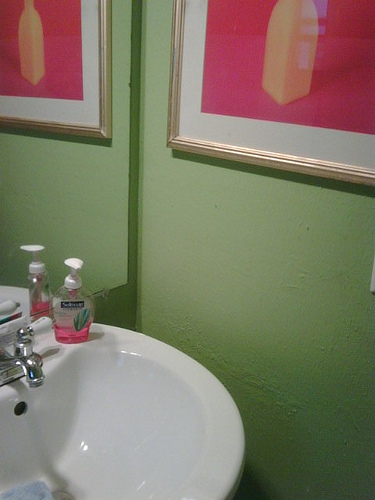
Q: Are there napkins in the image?
A: No, there are no napkins.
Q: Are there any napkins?
A: No, there are no napkins.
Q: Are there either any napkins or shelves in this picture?
A: No, there are no napkins or shelves.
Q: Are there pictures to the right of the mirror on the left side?
A: Yes, there is a picture to the right of the mirror.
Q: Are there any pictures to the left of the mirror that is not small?
A: No, the picture is to the right of the mirror.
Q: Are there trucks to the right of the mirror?
A: No, there is a picture to the right of the mirror.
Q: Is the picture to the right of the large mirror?
A: Yes, the picture is to the right of the mirror.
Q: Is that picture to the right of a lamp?
A: No, the picture is to the right of the mirror.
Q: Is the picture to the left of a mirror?
A: No, the picture is to the right of a mirror.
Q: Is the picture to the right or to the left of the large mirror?
A: The picture is to the right of the mirror.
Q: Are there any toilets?
A: No, there are no toilets.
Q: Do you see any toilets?
A: No, there are no toilets.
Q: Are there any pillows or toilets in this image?
A: No, there are no toilets or pillows.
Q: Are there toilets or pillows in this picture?
A: No, there are no toilets or pillows.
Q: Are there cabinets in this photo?
A: No, there are no cabinets.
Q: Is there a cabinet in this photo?
A: No, there are no cabinets.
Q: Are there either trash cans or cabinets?
A: No, there are no cabinets or trash cans.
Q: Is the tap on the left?
A: Yes, the tap is on the left of the image.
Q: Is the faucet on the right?
A: No, the faucet is on the left of the image.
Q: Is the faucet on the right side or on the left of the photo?
A: The faucet is on the left of the image.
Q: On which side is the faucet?
A: The faucet is on the left of the image.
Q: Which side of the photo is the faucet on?
A: The faucet is on the left of the image.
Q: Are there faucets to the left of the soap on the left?
A: Yes, there is a faucet to the left of the soap.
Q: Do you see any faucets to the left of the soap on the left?
A: Yes, there is a faucet to the left of the soap.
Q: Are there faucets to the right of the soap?
A: No, the faucet is to the left of the soap.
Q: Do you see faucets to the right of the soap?
A: No, the faucet is to the left of the soap.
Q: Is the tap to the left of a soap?
A: Yes, the tap is to the left of a soap.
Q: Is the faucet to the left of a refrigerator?
A: No, the faucet is to the left of a soap.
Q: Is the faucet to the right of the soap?
A: No, the faucet is to the left of the soap.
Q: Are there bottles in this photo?
A: Yes, there is a bottle.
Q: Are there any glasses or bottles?
A: Yes, there is a bottle.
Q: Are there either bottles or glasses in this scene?
A: Yes, there is a bottle.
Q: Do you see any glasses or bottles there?
A: Yes, there is a bottle.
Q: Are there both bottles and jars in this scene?
A: No, there is a bottle but no jars.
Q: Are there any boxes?
A: No, there are no boxes.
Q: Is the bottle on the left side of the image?
A: Yes, the bottle is on the left of the image.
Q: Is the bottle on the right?
A: No, the bottle is on the left of the image.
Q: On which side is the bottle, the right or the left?
A: The bottle is on the left of the image.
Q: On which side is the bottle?
A: The bottle is on the left of the image.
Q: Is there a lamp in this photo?
A: No, there are no lamps.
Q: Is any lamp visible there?
A: No, there are no lamps.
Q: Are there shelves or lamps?
A: No, there are no lamps or shelves.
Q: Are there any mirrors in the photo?
A: Yes, there is a mirror.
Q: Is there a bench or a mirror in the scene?
A: Yes, there is a mirror.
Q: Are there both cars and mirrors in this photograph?
A: No, there is a mirror but no cars.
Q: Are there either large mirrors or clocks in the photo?
A: Yes, there is a large mirror.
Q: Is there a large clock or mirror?
A: Yes, there is a large mirror.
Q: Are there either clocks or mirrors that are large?
A: Yes, the mirror is large.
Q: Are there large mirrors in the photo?
A: Yes, there is a large mirror.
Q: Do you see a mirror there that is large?
A: Yes, there is a mirror that is large.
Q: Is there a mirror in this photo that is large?
A: Yes, there is a mirror that is large.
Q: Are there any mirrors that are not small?
A: Yes, there is a large mirror.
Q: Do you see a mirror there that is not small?
A: Yes, there is a large mirror.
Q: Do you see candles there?
A: No, there are no candles.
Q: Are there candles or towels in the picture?
A: No, there are no candles or towels.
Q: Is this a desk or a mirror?
A: This is a mirror.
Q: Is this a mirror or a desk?
A: This is a mirror.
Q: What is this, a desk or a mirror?
A: This is a mirror.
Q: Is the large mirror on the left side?
A: Yes, the mirror is on the left of the image.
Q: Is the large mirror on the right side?
A: No, the mirror is on the left of the image.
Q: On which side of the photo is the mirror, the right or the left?
A: The mirror is on the left of the image.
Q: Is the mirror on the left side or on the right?
A: The mirror is on the left of the image.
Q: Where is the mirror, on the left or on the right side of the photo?
A: The mirror is on the left of the image.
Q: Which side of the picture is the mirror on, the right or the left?
A: The mirror is on the left of the image.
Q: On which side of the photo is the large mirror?
A: The mirror is on the left of the image.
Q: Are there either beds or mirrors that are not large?
A: No, there is a mirror but it is large.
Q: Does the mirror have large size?
A: Yes, the mirror is large.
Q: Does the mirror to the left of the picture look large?
A: Yes, the mirror is large.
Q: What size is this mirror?
A: The mirror is large.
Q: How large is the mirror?
A: The mirror is large.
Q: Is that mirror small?
A: No, the mirror is large.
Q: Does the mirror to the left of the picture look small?
A: No, the mirror is large.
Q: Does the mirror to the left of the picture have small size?
A: No, the mirror is large.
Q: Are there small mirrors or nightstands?
A: No, there is a mirror but it is large.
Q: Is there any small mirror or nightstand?
A: No, there is a mirror but it is large.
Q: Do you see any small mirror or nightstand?
A: No, there is a mirror but it is large.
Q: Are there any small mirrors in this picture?
A: No, there is a mirror but it is large.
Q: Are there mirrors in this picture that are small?
A: No, there is a mirror but it is large.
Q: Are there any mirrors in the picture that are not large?
A: No, there is a mirror but it is large.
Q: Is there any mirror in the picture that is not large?
A: No, there is a mirror but it is large.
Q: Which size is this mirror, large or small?
A: The mirror is large.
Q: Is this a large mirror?
A: Yes, this is a large mirror.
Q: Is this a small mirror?
A: No, this is a large mirror.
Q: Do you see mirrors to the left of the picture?
A: Yes, there is a mirror to the left of the picture.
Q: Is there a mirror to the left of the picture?
A: Yes, there is a mirror to the left of the picture.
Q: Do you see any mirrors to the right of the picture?
A: No, the mirror is to the left of the picture.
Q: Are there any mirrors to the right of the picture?
A: No, the mirror is to the left of the picture.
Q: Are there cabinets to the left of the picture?
A: No, there is a mirror to the left of the picture.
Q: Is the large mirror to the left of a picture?
A: Yes, the mirror is to the left of a picture.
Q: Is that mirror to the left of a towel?
A: No, the mirror is to the left of a picture.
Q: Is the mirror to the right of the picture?
A: No, the mirror is to the left of the picture.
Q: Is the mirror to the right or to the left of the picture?
A: The mirror is to the left of the picture.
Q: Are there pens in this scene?
A: No, there are no pens.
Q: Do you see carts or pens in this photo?
A: No, there are no pens or carts.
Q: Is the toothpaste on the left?
A: Yes, the toothpaste is on the left of the image.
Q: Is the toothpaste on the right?
A: No, the toothpaste is on the left of the image.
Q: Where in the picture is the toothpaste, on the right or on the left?
A: The toothpaste is on the left of the image.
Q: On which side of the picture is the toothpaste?
A: The toothpaste is on the left of the image.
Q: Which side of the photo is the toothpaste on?
A: The toothpaste is on the left of the image.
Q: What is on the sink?
A: The toothpaste is on the sink.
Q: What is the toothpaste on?
A: The toothpaste is on the sink.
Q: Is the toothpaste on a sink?
A: Yes, the toothpaste is on a sink.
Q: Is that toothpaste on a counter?
A: No, the toothpaste is on a sink.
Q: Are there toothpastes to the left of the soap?
A: Yes, there is a toothpaste to the left of the soap.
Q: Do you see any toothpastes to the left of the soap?
A: Yes, there is a toothpaste to the left of the soap.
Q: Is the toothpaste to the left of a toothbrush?
A: No, the toothpaste is to the left of the soap.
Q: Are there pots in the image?
A: No, there are no pots.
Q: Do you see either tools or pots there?
A: No, there are no pots or tools.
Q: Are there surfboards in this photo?
A: No, there are no surfboards.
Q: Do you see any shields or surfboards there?
A: No, there are no surfboards or shields.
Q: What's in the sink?
A: The drain is in the sink.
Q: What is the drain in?
A: The drain is in the sink.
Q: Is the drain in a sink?
A: Yes, the drain is in a sink.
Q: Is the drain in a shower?
A: No, the drain is in a sink.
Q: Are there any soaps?
A: Yes, there is a soap.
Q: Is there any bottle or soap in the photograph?
A: Yes, there is a soap.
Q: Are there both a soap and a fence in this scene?
A: No, there is a soap but no fences.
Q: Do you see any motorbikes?
A: No, there are no motorbikes.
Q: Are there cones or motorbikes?
A: No, there are no motorbikes or cones.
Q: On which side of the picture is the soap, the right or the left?
A: The soap is on the left of the image.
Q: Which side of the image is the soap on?
A: The soap is on the left of the image.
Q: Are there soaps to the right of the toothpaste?
A: Yes, there is a soap to the right of the toothpaste.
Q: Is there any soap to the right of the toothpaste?
A: Yes, there is a soap to the right of the toothpaste.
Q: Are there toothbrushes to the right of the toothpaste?
A: No, there is a soap to the right of the toothpaste.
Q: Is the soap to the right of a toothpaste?
A: Yes, the soap is to the right of a toothpaste.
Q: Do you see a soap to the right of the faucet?
A: Yes, there is a soap to the right of the faucet.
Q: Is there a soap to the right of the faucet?
A: Yes, there is a soap to the right of the faucet.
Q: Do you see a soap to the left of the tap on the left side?
A: No, the soap is to the right of the faucet.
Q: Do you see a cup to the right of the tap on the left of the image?
A: No, there is a soap to the right of the tap.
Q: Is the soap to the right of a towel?
A: No, the soap is to the right of the tap.